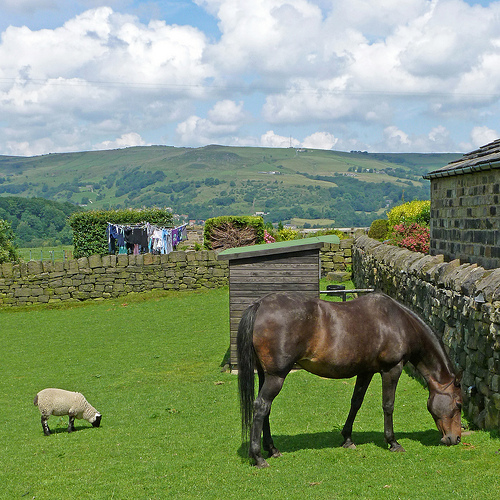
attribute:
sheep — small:
[22, 372, 117, 447]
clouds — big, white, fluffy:
[42, 4, 394, 109]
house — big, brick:
[410, 165, 497, 231]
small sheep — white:
[27, 385, 106, 436]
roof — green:
[217, 232, 342, 255]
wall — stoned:
[441, 184, 496, 280]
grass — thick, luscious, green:
[0, 276, 498, 498]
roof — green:
[217, 233, 352, 255]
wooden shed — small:
[217, 234, 338, 368]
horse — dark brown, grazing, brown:
[233, 286, 466, 470]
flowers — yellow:
[385, 200, 431, 225]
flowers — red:
[383, 218, 434, 253]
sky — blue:
[2, 7, 497, 160]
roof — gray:
[428, 141, 499, 177]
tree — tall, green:
[69, 208, 172, 258]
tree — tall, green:
[307, 186, 313, 193]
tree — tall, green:
[227, 181, 234, 188]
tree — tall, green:
[80, 197, 88, 206]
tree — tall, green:
[330, 203, 360, 226]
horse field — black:
[230, 277, 458, 470]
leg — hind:
[239, 320, 314, 458]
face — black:
[91, 415, 101, 425]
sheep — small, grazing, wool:
[30, 387, 103, 437]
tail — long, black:
[234, 302, 255, 455]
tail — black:
[210, 282, 286, 450]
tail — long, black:
[241, 304, 257, 432]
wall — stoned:
[71, 240, 242, 297]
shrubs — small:
[175, 175, 343, 210]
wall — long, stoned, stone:
[351, 232, 499, 427]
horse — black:
[223, 292, 475, 463]